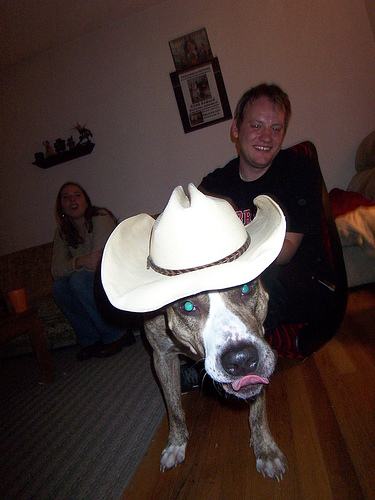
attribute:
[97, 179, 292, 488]
dog — standing, gray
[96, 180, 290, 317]
cowboy hat — white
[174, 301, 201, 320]
eye — blue, turquoise, teal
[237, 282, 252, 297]
eye — blue, turquoise, teal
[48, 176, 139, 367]
girl — sitting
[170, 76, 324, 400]
boy — sitting, smiling, seated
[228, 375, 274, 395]
tongue — out, pink, red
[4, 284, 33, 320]
cup — orange, red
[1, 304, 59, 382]
coffee table — wooden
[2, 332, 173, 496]
rug — grey, striped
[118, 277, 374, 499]
floor — wood, brown, wooden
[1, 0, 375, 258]
wall — white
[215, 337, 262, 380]
nose — black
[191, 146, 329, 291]
shirt — black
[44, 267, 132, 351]
pants — blue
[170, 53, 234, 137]
newspaper article — framed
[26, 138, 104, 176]
shelf — small